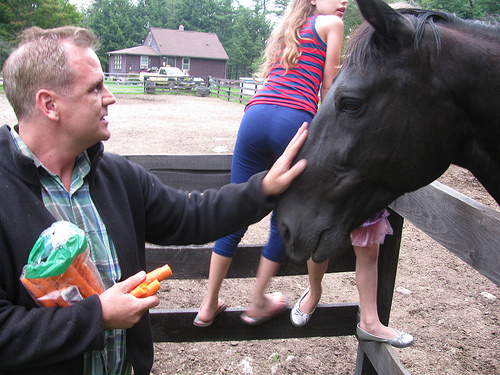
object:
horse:
[273, 0, 500, 265]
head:
[270, 0, 464, 265]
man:
[0, 23, 310, 375]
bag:
[19, 219, 107, 308]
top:
[24, 219, 90, 280]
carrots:
[126, 263, 173, 299]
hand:
[89, 269, 161, 331]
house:
[103, 23, 230, 86]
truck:
[139, 64, 192, 90]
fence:
[103, 72, 208, 84]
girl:
[192, 0, 349, 329]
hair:
[250, 0, 316, 85]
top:
[243, 13, 328, 118]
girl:
[288, 187, 415, 349]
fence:
[1, 153, 500, 373]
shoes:
[360, 303, 421, 330]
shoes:
[289, 287, 322, 329]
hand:
[258, 121, 309, 199]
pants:
[210, 102, 313, 264]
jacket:
[0, 122, 278, 374]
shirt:
[7, 124, 129, 375]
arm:
[0, 287, 104, 372]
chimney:
[178, 24, 185, 31]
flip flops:
[239, 292, 288, 326]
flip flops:
[192, 297, 229, 328]